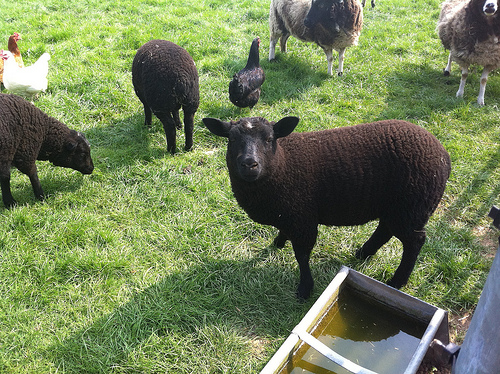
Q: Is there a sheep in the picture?
A: Yes, there is a sheep.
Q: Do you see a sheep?
A: Yes, there is a sheep.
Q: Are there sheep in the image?
A: Yes, there is a sheep.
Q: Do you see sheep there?
A: Yes, there is a sheep.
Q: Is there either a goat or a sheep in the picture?
A: Yes, there is a sheep.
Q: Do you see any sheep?
A: Yes, there is a sheep.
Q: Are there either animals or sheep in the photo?
A: Yes, there is a sheep.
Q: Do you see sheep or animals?
A: Yes, there is a sheep.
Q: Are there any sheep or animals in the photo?
A: Yes, there is a sheep.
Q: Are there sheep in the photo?
A: Yes, there is a sheep.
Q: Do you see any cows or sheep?
A: Yes, there is a sheep.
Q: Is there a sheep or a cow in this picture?
A: Yes, there is a sheep.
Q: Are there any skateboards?
A: No, there are no skateboards.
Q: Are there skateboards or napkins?
A: No, there are no skateboards or napkins.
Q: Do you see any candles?
A: No, there are no candles.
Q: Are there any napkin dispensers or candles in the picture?
A: No, there are no candles or napkin dispensers.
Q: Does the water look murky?
A: Yes, the water is murky.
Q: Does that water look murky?
A: Yes, the water is murky.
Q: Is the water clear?
A: No, the water is murky.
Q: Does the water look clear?
A: No, the water is murky.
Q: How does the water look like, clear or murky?
A: The water is murky.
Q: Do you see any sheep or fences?
A: Yes, there is a sheep.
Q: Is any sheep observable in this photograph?
A: Yes, there is a sheep.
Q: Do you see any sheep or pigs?
A: Yes, there is a sheep.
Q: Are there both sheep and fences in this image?
A: Yes, there are both a sheep and a fence.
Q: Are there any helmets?
A: No, there are no helmets.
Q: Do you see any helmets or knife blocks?
A: No, there are no helmets or knife blocks.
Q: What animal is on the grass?
A: The animal is chicken.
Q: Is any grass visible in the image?
A: Yes, there is grass.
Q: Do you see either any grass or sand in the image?
A: Yes, there is grass.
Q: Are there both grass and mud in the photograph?
A: No, there is grass but no mud.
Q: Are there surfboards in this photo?
A: No, there are no surfboards.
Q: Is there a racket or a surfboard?
A: No, there are no surfboards or rackets.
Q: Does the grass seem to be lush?
A: Yes, the grass is lush.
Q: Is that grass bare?
A: No, the grass is lush.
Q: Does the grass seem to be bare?
A: No, the grass is lush.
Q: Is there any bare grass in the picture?
A: No, there is grass but it is lush.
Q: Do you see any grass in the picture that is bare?
A: No, there is grass but it is lush.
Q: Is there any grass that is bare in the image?
A: No, there is grass but it is lush.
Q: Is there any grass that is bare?
A: No, there is grass but it is lush.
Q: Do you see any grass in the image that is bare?
A: No, there is grass but it is lush.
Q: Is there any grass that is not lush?
A: No, there is grass but it is lush.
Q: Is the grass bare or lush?
A: The grass is lush.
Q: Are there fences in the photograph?
A: Yes, there is a fence.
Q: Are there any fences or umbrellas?
A: Yes, there is a fence.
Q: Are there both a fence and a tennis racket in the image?
A: No, there is a fence but no rackets.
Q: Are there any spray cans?
A: No, there are no spray cans.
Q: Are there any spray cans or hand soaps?
A: No, there are no spray cans or hand soaps.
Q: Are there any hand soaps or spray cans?
A: No, there are no spray cans or hand soaps.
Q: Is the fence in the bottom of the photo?
A: Yes, the fence is in the bottom of the image.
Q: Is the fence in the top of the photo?
A: No, the fence is in the bottom of the image.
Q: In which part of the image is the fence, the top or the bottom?
A: The fence is in the bottom of the image.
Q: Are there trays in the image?
A: No, there are no trays.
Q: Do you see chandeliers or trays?
A: No, there are no trays or chandeliers.